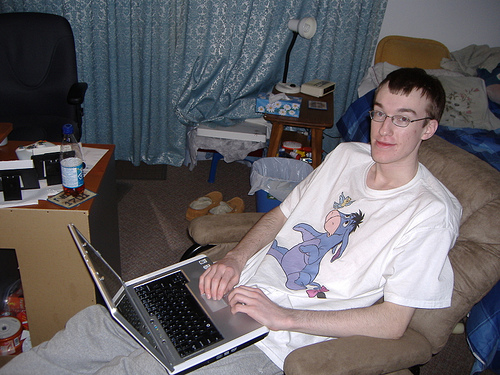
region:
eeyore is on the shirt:
[319, 207, 361, 237]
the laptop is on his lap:
[218, 341, 265, 363]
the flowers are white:
[280, 104, 297, 117]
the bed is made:
[461, 126, 494, 156]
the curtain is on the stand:
[197, 78, 247, 135]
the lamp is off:
[300, 16, 319, 37]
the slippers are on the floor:
[198, 187, 243, 217]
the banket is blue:
[351, 107, 368, 130]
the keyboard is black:
[163, 288, 191, 320]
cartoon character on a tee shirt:
[263, 194, 365, 306]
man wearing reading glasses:
[371, 103, 455, 142]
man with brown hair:
[359, 49, 463, 147]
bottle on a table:
[49, 129, 100, 195]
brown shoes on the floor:
[188, 195, 248, 221]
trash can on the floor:
[244, 144, 329, 197]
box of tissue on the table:
[253, 78, 308, 123]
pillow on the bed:
[394, 50, 494, 133]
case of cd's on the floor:
[5, 315, 27, 356]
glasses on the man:
[367, 108, 430, 133]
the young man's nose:
[373, 117, 391, 140]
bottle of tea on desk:
[61, 119, 95, 197]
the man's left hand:
[226, 275, 286, 340]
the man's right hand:
[198, 251, 237, 306]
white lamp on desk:
[285, 4, 322, 43]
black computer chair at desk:
[0, 9, 96, 128]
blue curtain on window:
[96, 0, 192, 165]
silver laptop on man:
[63, 220, 269, 373]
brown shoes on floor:
[181, 184, 246, 219]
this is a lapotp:
[71, 234, 258, 365]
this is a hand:
[199, 205, 256, 287]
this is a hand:
[230, 284, 359, 331]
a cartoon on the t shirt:
[281, 197, 358, 280]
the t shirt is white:
[386, 184, 416, 248]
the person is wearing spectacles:
[368, 101, 408, 128]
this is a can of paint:
[2, 320, 22, 358]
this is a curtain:
[127, 33, 197, 77]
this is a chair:
[0, 18, 84, 137]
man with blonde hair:
[356, 57, 453, 171]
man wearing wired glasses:
[368, 104, 439, 128]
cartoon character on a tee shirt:
[247, 193, 378, 278]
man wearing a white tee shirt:
[253, 162, 450, 346]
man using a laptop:
[178, 252, 271, 344]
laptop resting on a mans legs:
[45, 215, 288, 372]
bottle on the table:
[50, 119, 89, 209]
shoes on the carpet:
[186, 185, 245, 225]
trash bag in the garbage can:
[252, 152, 310, 203]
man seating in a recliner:
[218, 160, 445, 365]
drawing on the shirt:
[220, 186, 377, 307]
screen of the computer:
[63, 236, 155, 352]